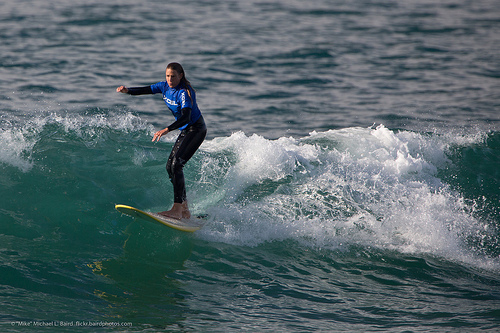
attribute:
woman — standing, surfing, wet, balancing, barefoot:
[109, 69, 225, 220]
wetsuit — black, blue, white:
[126, 82, 228, 212]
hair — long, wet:
[126, 72, 225, 112]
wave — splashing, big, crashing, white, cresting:
[4, 112, 483, 236]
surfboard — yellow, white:
[90, 192, 246, 239]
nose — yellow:
[108, 195, 156, 214]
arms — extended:
[85, 60, 222, 145]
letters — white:
[153, 93, 188, 104]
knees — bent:
[146, 142, 184, 170]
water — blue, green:
[4, 2, 492, 328]